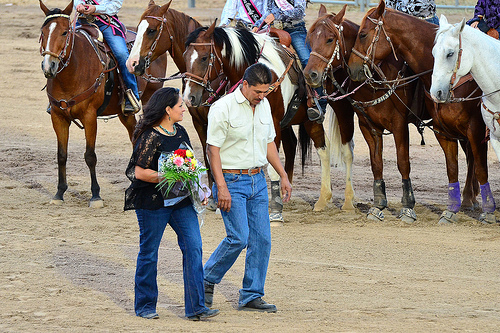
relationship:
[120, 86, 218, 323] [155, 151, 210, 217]
woman with flowers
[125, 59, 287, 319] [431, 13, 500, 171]
people walking in front of horse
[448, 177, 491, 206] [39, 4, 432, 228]
cloth on horse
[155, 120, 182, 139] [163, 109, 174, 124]
necklace and earring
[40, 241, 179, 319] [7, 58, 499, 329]
shadow in sand